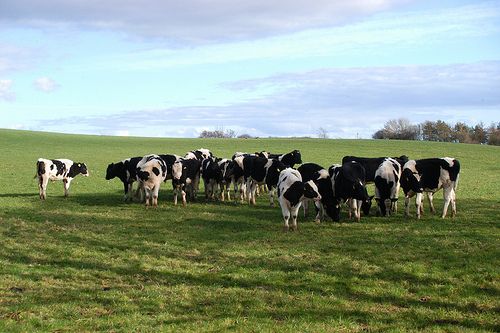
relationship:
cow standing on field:
[34, 155, 89, 199] [20, 205, 482, 331]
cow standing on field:
[371, 162, 399, 213] [5, 126, 490, 325]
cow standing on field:
[328, 161, 375, 221] [5, 126, 490, 325]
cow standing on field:
[276, 167, 322, 233] [306, 227, 448, 315]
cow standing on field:
[276, 167, 322, 233] [23, 235, 482, 320]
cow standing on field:
[168, 150, 200, 207] [5, 126, 490, 325]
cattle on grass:
[22, 133, 474, 233] [1, 126, 497, 330]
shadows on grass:
[4, 185, 496, 327] [1, 126, 497, 330]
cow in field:
[399, 157, 460, 219] [0, 200, 497, 330]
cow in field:
[270, 161, 322, 230] [0, 200, 497, 330]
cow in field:
[34, 155, 89, 199] [0, 200, 497, 330]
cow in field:
[103, 154, 145, 193] [0, 200, 497, 330]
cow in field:
[172, 158, 201, 208] [0, 200, 497, 330]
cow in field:
[399, 157, 460, 219] [85, 154, 420, 273]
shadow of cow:
[0, 185, 35, 202] [33, 151, 89, 193]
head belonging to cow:
[360, 194, 374, 217] [322, 161, 375, 223]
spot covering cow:
[49, 161, 55, 171] [35, 156, 90, 198]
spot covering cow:
[122, 156, 132, 169] [105, 154, 145, 198]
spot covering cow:
[151, 167, 160, 176] [134, 154, 202, 206]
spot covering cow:
[280, 176, 287, 181] [275, 167, 322, 230]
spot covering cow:
[390, 160, 401, 172] [372, 157, 402, 219]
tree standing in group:
[227, 127, 234, 138] [192, 126, 235, 138]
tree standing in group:
[201, 130, 209, 138] [192, 126, 235, 138]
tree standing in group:
[383, 117, 410, 140] [370, 117, 485, 141]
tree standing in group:
[372, 127, 388, 140] [370, 117, 485, 141]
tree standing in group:
[435, 120, 443, 140] [370, 117, 485, 141]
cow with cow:
[398, 153, 460, 216] [277, 168, 321, 228]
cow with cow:
[34, 155, 87, 199] [297, 163, 341, 223]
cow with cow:
[297, 163, 341, 223] [103, 153, 142, 195]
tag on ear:
[78, 162, 82, 167] [70, 161, 86, 175]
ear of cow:
[70, 161, 86, 175] [29, 151, 87, 201]